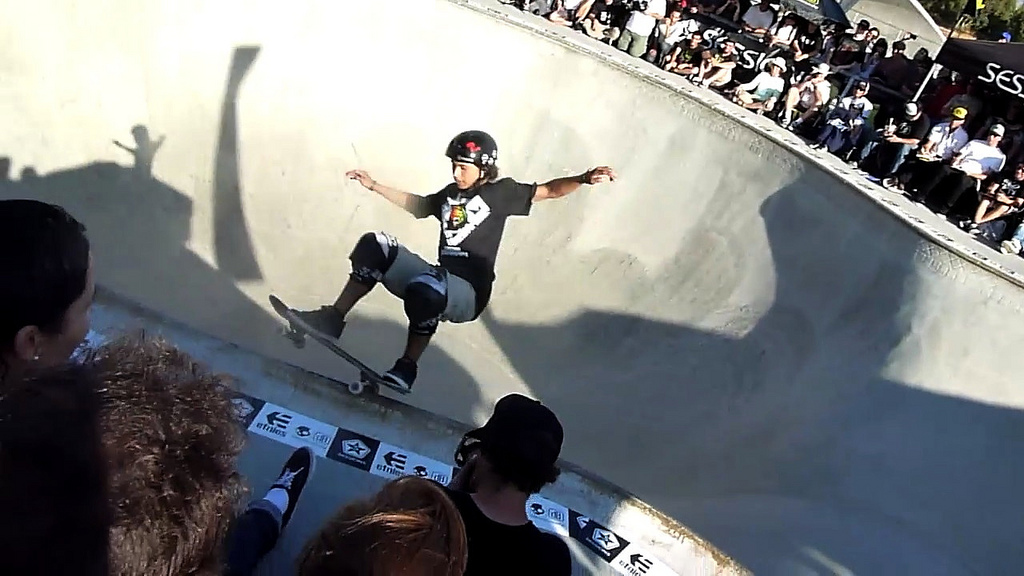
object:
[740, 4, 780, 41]
person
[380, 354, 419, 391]
shoe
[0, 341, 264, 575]
person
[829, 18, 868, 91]
person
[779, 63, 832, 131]
person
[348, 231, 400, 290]
knee pad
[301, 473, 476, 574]
person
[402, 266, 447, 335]
knee pad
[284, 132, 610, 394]
man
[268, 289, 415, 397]
skate boarder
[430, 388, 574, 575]
person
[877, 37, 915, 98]
person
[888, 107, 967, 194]
person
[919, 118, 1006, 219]
person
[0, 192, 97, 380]
person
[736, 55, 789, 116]
person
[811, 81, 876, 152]
person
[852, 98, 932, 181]
person